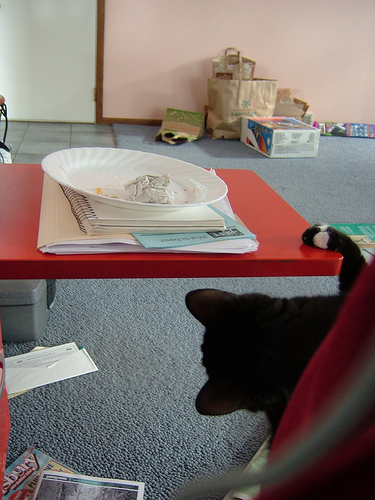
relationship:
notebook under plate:
[73, 193, 232, 237] [42, 140, 236, 219]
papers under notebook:
[40, 232, 250, 266] [73, 193, 232, 237]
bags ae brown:
[208, 42, 311, 144] [214, 87, 248, 107]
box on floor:
[238, 109, 323, 166] [4, 111, 375, 500]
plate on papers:
[42, 140, 236, 219] [40, 232, 250, 266]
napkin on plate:
[111, 166, 180, 208] [42, 140, 236, 219]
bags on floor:
[208, 42, 311, 144] [4, 111, 375, 500]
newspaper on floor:
[327, 217, 374, 255] [4, 111, 375, 500]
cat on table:
[171, 221, 359, 420] [2, 160, 345, 282]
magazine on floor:
[3, 442, 156, 499] [4, 111, 375, 500]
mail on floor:
[2, 336, 107, 399] [4, 111, 375, 500]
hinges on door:
[89, 83, 103, 106] [0, 3, 107, 133]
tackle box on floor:
[0, 278, 67, 341] [4, 111, 375, 500]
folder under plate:
[40, 190, 84, 260] [42, 140, 236, 219]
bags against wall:
[208, 42, 311, 144] [104, 2, 374, 135]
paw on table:
[303, 219, 340, 253] [2, 160, 345, 282]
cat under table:
[171, 221, 359, 420] [2, 160, 345, 282]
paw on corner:
[303, 219, 340, 253] [291, 237, 353, 275]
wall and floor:
[104, 2, 374, 135] [4, 111, 375, 500]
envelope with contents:
[2, 346, 99, 399] [6, 341, 79, 368]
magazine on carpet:
[3, 442, 156, 499] [279, 137, 373, 227]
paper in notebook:
[140, 227, 252, 248] [73, 193, 232, 237]